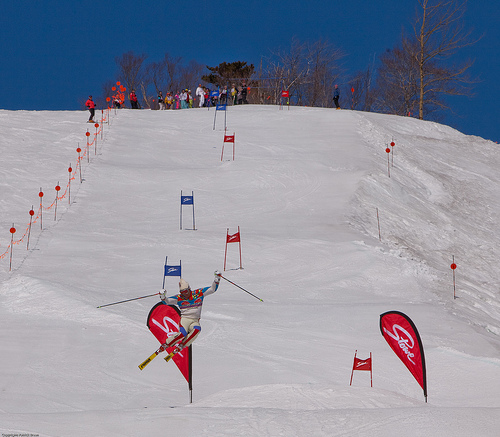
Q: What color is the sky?
A: Blue.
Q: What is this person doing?
A: Skiing.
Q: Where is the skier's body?
A: In the air.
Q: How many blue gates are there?
A: Three.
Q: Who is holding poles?
A: The skier.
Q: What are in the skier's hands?
A: Ski poles.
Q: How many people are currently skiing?
A: One.